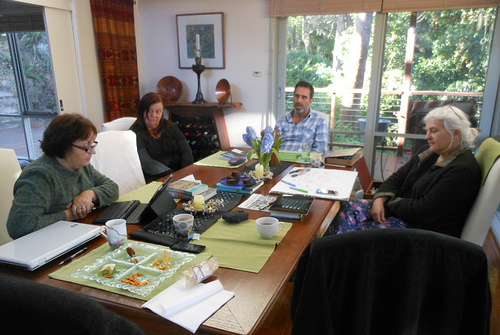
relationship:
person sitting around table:
[12, 114, 120, 241] [8, 144, 345, 334]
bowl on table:
[72, 237, 197, 302] [8, 144, 345, 334]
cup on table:
[255, 213, 287, 241] [8, 144, 345, 334]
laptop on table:
[1, 217, 107, 281] [8, 144, 345, 334]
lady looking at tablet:
[337, 102, 484, 243] [268, 194, 315, 218]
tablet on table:
[268, 194, 315, 218] [8, 144, 345, 334]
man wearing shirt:
[267, 81, 331, 153] [275, 111, 330, 158]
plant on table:
[239, 121, 287, 179] [8, 144, 345, 334]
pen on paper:
[289, 186, 311, 196] [263, 160, 361, 205]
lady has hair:
[337, 102, 484, 243] [425, 100, 477, 152]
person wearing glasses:
[12, 114, 120, 241] [66, 138, 99, 152]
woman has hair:
[127, 95, 198, 175] [142, 89, 164, 118]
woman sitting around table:
[127, 95, 198, 175] [8, 144, 345, 334]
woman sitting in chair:
[127, 95, 198, 175] [100, 114, 145, 131]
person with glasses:
[12, 114, 120, 241] [66, 138, 99, 152]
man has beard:
[267, 81, 331, 153] [292, 104, 311, 116]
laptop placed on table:
[1, 217, 107, 281] [8, 144, 345, 334]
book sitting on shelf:
[190, 119, 206, 147] [163, 95, 234, 151]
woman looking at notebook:
[337, 102, 484, 243] [263, 160, 361, 205]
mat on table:
[186, 214, 296, 282] [8, 144, 345, 334]